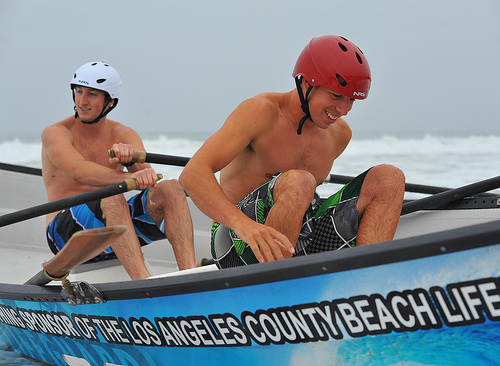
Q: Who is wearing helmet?
A: Boater.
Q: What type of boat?
A: Row.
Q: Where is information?
A: Side of boat.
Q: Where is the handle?
A: On paddle.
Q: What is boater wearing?
A: Swim trunks.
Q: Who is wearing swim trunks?
A: A boater.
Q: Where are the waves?
A: Side of boaters.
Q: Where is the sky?
A: Above boater.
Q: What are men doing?
A: Rowing.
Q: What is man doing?
A: Smiling.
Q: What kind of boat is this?
A: A canoe.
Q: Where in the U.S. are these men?
A: Los Angeles.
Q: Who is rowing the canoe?
A: The man in back.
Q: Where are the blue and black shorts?
A: On the man in the back.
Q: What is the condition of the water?
A: Turbulent.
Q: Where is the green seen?
A: On the front man's shorts.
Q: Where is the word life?
A: Right side of canoe.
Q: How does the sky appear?
A: Gray.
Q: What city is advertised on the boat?
A: Los Angeles.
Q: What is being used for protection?
A: Helmets.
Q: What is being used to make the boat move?
A: An Oar.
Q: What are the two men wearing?
A: Swim trunks.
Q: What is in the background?
A: Waves.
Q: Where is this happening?
A: In the ocean.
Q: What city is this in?
A: Los Angeles.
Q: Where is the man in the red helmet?
A: In front.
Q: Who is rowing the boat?
A: Two boys.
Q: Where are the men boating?
A: On the water.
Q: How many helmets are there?
A: 2.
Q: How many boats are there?
A: 1.